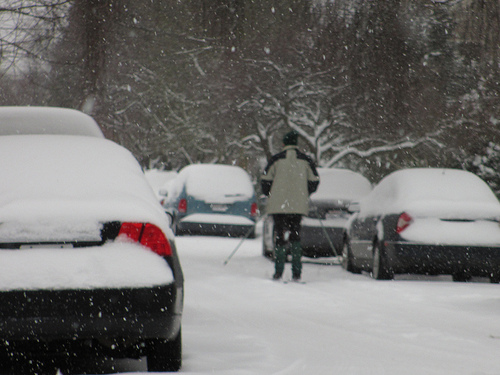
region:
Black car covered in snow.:
[6, 177, 171, 344]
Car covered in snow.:
[4, 88, 116, 137]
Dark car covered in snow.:
[360, 178, 451, 265]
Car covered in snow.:
[263, 184, 342, 246]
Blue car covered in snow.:
[164, 168, 259, 268]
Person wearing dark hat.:
[277, 124, 317, 161]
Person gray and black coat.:
[258, 142, 325, 204]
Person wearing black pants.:
[265, 217, 332, 245]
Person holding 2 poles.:
[228, 197, 354, 273]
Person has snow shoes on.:
[250, 263, 312, 292]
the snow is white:
[287, 336, 293, 344]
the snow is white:
[299, 345, 344, 370]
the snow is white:
[281, 331, 326, 359]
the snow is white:
[296, 303, 380, 373]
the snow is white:
[288, 310, 334, 367]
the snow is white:
[282, 317, 305, 359]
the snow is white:
[271, 325, 319, 370]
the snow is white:
[266, 348, 291, 367]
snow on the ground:
[266, 285, 371, 349]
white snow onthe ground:
[262, 297, 359, 372]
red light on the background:
[98, 203, 182, 284]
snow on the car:
[38, 113, 143, 218]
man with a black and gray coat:
[207, 126, 348, 264]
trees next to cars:
[329, 74, 414, 121]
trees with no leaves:
[193, 19, 374, 119]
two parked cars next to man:
[334, 126, 476, 271]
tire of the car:
[331, 235, 398, 305]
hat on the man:
[265, 123, 309, 166]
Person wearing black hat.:
[273, 126, 293, 140]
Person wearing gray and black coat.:
[258, 157, 334, 207]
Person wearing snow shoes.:
[256, 257, 301, 287]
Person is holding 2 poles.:
[248, 195, 324, 272]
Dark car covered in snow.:
[356, 205, 462, 299]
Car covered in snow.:
[293, 167, 350, 293]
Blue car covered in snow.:
[184, 156, 248, 236]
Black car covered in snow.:
[61, 214, 166, 329]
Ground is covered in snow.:
[208, 262, 335, 364]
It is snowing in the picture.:
[120, 10, 414, 110]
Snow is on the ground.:
[224, 292, 419, 369]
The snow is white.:
[234, 294, 409, 374]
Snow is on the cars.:
[2, 100, 499, 368]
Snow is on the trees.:
[159, 40, 376, 130]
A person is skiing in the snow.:
[210, 120, 365, 290]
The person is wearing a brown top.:
[215, 123, 355, 295]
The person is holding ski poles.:
[208, 123, 350, 292]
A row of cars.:
[1, 102, 498, 374]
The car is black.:
[0, 125, 200, 372]